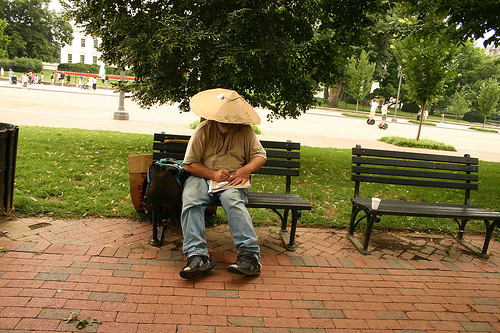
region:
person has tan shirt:
[191, 131, 261, 192]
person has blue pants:
[155, 175, 255, 257]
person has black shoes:
[155, 257, 267, 288]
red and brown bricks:
[290, 253, 367, 330]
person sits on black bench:
[140, 134, 312, 252]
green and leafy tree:
[60, 4, 337, 114]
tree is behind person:
[92, 10, 327, 122]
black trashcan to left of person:
[0, 121, 48, 215]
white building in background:
[35, 14, 117, 56]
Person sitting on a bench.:
[173, 84, 263, 277]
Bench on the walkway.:
[342, 133, 498, 255]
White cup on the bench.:
[366, 188, 383, 211]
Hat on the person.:
[190, 83, 260, 139]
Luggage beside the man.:
[141, 141, 186, 226]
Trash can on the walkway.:
[0, 117, 20, 222]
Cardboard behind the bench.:
[122, 147, 154, 212]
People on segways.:
[362, 90, 395, 131]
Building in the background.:
[54, 23, 136, 72]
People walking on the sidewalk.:
[5, 63, 100, 90]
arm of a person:
[235, 141, 287, 185]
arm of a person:
[167, 148, 214, 180]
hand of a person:
[213, 166, 233, 181]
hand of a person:
[225, 162, 253, 190]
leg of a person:
[179, 173, 216, 275]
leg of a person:
[223, 179, 267, 284]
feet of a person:
[177, 259, 212, 280]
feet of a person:
[226, 252, 266, 290]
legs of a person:
[172, 176, 273, 290]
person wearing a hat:
[176, 78, 264, 140]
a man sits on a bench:
[136, 83, 316, 283]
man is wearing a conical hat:
[174, 84, 265, 279]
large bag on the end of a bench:
[142, 128, 314, 253]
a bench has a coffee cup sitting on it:
[341, 141, 498, 260]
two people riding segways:
[364, 95, 400, 134]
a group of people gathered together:
[6, 66, 112, 91]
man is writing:
[174, 82, 270, 280]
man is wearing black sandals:
[171, 83, 270, 281]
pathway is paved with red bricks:
[2, 219, 499, 331]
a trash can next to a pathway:
[0, 120, 20, 218]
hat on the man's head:
[187, 91, 263, 130]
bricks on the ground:
[91, 285, 204, 312]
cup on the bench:
[360, 191, 391, 217]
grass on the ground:
[30, 156, 116, 197]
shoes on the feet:
[175, 249, 257, 279]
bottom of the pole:
[115, 104, 131, 125]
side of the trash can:
[0, 119, 45, 219]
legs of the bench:
[342, 215, 379, 252]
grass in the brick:
[57, 305, 91, 330]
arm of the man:
[180, 161, 233, 180]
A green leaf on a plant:
[228, 23, 234, 29]